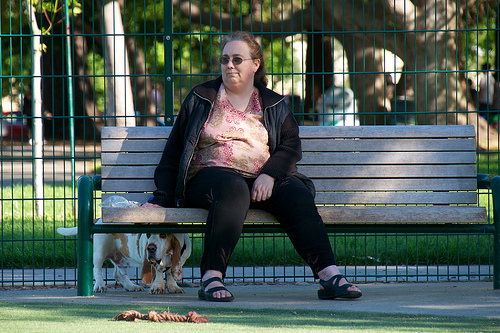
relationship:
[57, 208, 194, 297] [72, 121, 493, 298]
dog under bench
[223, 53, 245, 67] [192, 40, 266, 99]
sunglasses on face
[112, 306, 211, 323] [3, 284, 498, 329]
toy on ground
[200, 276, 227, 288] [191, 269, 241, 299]
black strap on sandal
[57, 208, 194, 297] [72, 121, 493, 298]
dog hiding under bench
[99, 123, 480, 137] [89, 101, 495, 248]
slats of bench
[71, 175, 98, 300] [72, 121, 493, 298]
green support of bench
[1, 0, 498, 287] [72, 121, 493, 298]
fence behind bench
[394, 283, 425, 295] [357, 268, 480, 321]
surface of path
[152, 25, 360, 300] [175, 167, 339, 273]
woman wearing pants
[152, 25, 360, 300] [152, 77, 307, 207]
woman wearing black coat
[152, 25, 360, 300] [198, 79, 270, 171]
woman wearing shirt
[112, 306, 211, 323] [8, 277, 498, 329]
toy on grass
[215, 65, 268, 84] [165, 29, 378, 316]
head of woman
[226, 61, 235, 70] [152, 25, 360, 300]
nose of woman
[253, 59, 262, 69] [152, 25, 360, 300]
ear of woman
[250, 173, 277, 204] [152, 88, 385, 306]
hand of woman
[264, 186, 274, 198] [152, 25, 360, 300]
finger of woman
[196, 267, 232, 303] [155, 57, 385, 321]
foot of woman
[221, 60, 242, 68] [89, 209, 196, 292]
nose of dog